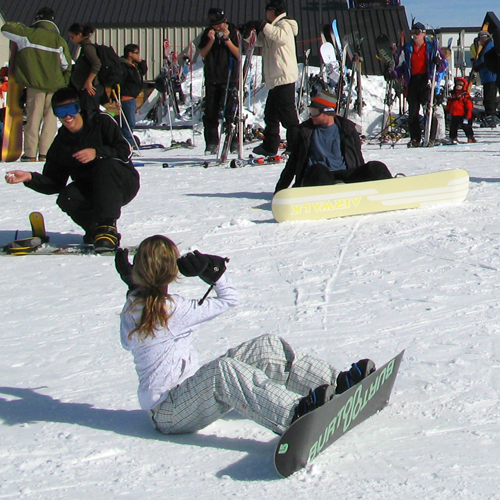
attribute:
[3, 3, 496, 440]
people — grouped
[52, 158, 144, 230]
pants — black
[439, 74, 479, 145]
person — wearing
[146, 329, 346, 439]
pants — plaid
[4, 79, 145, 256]
man — kneeling down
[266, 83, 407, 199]
man — wearing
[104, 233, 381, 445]
skier — wearing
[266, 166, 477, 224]
snowboard — long, yellow, white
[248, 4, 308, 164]
skier — wearing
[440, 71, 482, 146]
child — wearing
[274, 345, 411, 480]
snowboard — black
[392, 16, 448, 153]
man — wearing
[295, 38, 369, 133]
snowboards — grouped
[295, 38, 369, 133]
skiis — grouped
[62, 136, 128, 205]
snow attire — black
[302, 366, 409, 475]
lettering — green